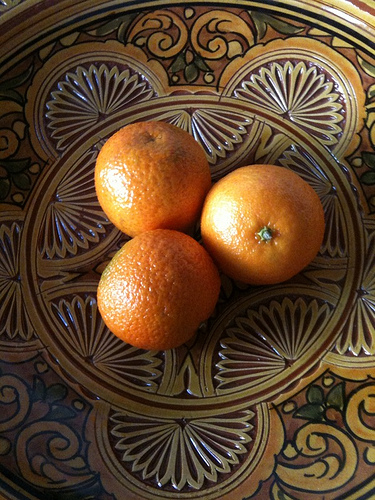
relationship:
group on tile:
[84, 122, 331, 356] [0, 1, 374, 498]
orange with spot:
[93, 121, 325, 351] [130, 118, 187, 165]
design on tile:
[190, 7, 256, 59] [0, 1, 374, 498]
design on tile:
[125, 7, 190, 59] [0, 1, 374, 498]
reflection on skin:
[209, 194, 238, 238] [200, 163, 327, 283]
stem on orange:
[256, 223, 275, 242] [201, 164, 327, 281]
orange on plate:
[93, 121, 325, 351] [0, 2, 372, 499]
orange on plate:
[201, 164, 327, 281] [0, 2, 372, 499]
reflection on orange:
[100, 160, 138, 207] [93, 121, 325, 351]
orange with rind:
[93, 121, 325, 351] [97, 228, 215, 345]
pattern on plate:
[17, 418, 97, 490] [0, 2, 372, 499]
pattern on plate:
[293, 383, 346, 422] [0, 2, 372, 499]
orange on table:
[201, 164, 327, 281] [2, 1, 373, 498]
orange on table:
[93, 121, 325, 351] [2, 1, 373, 498]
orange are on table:
[93, 121, 325, 351] [2, 1, 373, 498]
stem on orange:
[257, 226, 275, 242] [93, 121, 325, 351]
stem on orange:
[257, 226, 275, 242] [193, 151, 325, 290]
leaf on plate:
[289, 373, 348, 420] [0, 2, 372, 499]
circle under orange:
[24, 96, 364, 414] [93, 121, 325, 351]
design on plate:
[268, 417, 362, 495] [0, 2, 372, 499]